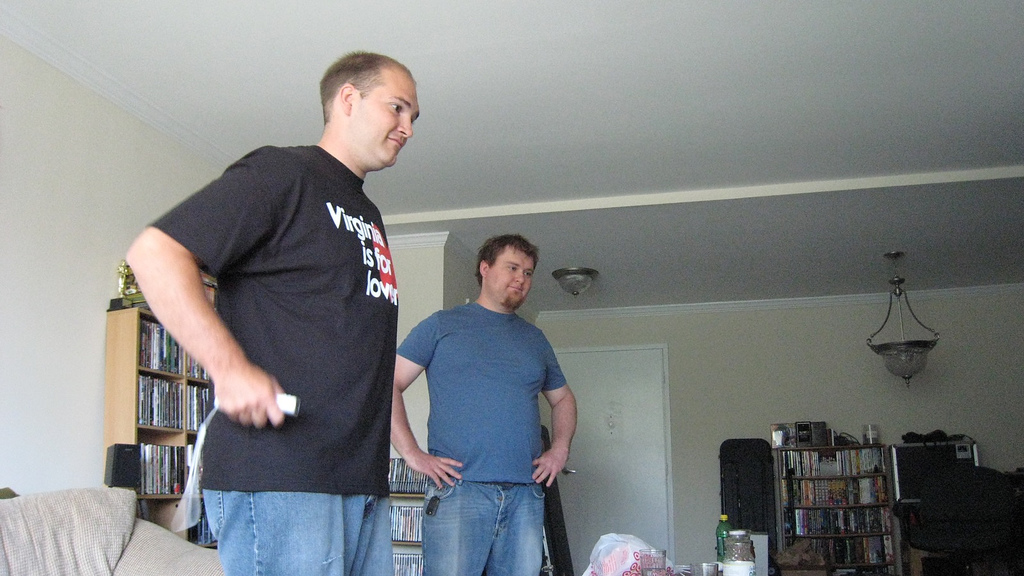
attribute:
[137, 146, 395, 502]
t shirt — black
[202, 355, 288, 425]
hand — man's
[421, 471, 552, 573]
jeans — blue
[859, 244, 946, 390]
light fixture — hanging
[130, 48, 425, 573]
person — playing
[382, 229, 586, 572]
person — standing